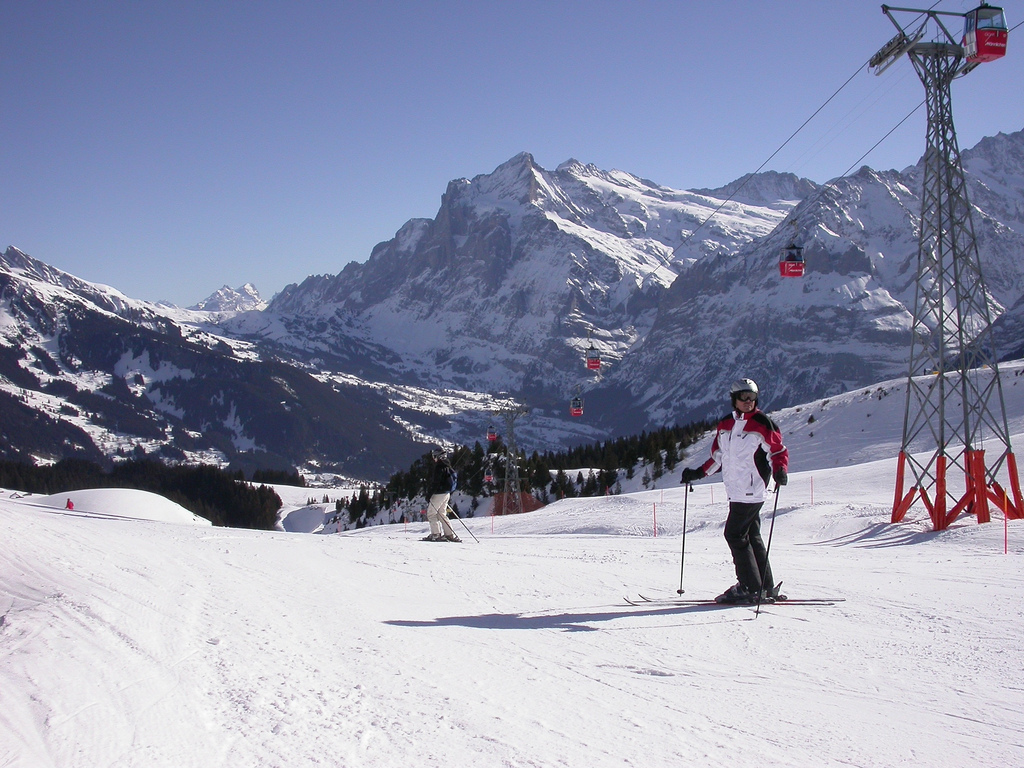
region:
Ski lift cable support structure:
[882, 3, 1020, 520]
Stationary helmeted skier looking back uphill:
[672, 375, 854, 611]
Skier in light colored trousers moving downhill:
[413, 436, 478, 541]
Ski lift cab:
[964, 6, 1009, 64]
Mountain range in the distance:
[5, 148, 1009, 384]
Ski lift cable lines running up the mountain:
[464, 9, 1022, 456]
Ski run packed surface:
[195, 528, 1015, 745]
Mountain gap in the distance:
[21, 237, 382, 318]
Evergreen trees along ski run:
[338, 433, 694, 511]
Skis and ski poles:
[672, 471, 856, 615]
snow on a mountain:
[436, 200, 747, 475]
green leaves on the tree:
[145, 451, 270, 543]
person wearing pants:
[422, 436, 457, 547]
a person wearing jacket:
[417, 435, 478, 537]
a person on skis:
[410, 435, 458, 562]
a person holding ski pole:
[395, 461, 514, 570]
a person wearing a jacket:
[683, 364, 798, 602]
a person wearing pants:
[667, 383, 788, 576]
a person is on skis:
[686, 363, 817, 605]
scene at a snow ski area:
[183, 0, 1016, 765]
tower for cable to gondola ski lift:
[867, 0, 1020, 533]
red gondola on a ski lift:
[964, 7, 1007, 65]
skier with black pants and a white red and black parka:
[624, 374, 846, 618]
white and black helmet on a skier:
[728, 378, 760, 423]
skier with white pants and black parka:
[415, 444, 482, 547]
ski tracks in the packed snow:
[10, 507, 1017, 765]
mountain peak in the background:
[190, 280, 271, 315]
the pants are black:
[719, 498, 773, 588]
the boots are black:
[719, 580, 773, 600]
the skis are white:
[620, 593, 843, 609]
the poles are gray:
[677, 477, 783, 611]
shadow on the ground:
[380, 606, 713, 632]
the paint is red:
[889, 445, 1022, 528]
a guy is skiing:
[422, 451, 479, 547]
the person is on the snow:
[676, 376, 793, 607]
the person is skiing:
[659, 377, 816, 611]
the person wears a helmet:
[726, 377, 745, 387]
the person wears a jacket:
[704, 413, 788, 502]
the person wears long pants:
[721, 503, 785, 601]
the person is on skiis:
[622, 590, 851, 603]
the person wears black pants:
[727, 490, 785, 589]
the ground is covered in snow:
[12, 480, 1003, 766]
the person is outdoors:
[651, 372, 826, 620]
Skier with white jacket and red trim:
[672, 366, 796, 614]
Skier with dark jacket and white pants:
[409, 439, 464, 550]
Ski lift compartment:
[773, 234, 812, 279]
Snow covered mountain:
[222, 139, 791, 416]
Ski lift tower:
[873, 7, 1007, 545]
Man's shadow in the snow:
[374, 595, 735, 641]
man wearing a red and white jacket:
[699, 407, 780, 500]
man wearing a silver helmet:
[732, 370, 758, 406]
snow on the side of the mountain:
[480, 161, 605, 259]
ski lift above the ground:
[764, 241, 813, 284]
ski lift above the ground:
[581, 337, 611, 372]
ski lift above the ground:
[562, 395, 592, 419]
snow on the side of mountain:
[95, 342, 197, 413]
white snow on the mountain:
[468, 238, 526, 281]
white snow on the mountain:
[468, 297, 506, 340]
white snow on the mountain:
[541, 332, 584, 378]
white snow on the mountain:
[377, 335, 400, 428]